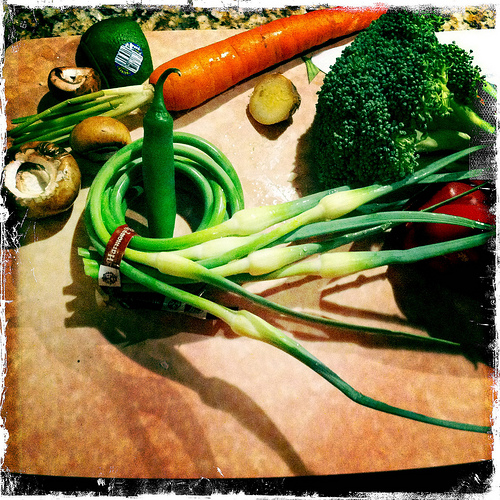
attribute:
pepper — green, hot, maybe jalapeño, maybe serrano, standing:
[135, 63, 185, 239]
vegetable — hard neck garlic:
[56, 123, 490, 439]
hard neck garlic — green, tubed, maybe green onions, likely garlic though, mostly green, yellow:
[62, 126, 494, 446]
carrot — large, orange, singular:
[8, 6, 392, 152]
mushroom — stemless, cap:
[4, 139, 83, 225]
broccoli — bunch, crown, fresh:
[306, 4, 494, 190]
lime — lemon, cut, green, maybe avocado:
[76, 12, 155, 89]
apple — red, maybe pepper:
[400, 178, 494, 251]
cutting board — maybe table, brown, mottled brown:
[7, 29, 491, 477]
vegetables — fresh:
[3, 8, 496, 435]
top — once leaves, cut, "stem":
[7, 73, 158, 160]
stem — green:
[130, 79, 156, 112]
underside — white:
[1, 153, 61, 201]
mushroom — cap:
[70, 113, 133, 167]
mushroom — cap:
[45, 63, 105, 105]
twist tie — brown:
[93, 224, 243, 332]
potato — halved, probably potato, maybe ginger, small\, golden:
[243, 70, 304, 130]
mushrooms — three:
[0, 52, 134, 217]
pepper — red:
[392, 168, 500, 272]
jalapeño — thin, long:
[141, 65, 186, 238]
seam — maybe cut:
[78, 37, 112, 90]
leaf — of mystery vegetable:
[298, 52, 322, 87]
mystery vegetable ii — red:
[391, 166, 497, 271]